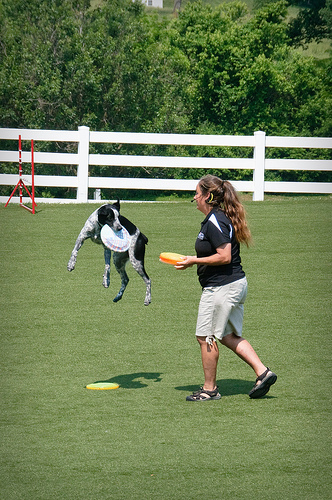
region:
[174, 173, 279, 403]
a woman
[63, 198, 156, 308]
a dog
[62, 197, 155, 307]
the dog is catching a frisbee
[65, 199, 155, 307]
the dog is in the air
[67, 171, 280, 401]
the woman is playing with a dog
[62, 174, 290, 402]
the woman tosses frisbees to the dog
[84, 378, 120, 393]
a yellow frisbee is on the ground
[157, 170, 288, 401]
the woman is holding a frisbee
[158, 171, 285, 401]
the woman is wearing a headset microphone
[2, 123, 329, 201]
a white fence beside the field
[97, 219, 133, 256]
a white frisbee in a dog's mouth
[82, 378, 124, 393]
a yellow frisbee on the ground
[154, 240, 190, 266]
an orange frisbee in a woman's hands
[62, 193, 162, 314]
a dog jumping with a frisbee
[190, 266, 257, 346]
tan shorts on a woman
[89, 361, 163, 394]
the shadow of a dog on the ground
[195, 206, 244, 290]
a black shirt on a woman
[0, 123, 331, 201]
a white wooden fence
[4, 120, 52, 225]
red metal poles near a fence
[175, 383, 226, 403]
a sandal on a woman's foot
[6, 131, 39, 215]
red metal obstacle course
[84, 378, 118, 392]
yellow and green frisbee on ground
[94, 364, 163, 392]
shadow of dog on ground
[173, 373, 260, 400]
shadow of woman on ground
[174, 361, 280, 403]
brown camp sandals on woman's feet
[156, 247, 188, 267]
two frisbees in woman's hands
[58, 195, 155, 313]
dog catching frisbee mid-flight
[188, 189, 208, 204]
face microphone on woman's head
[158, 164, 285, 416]
woman with long, brown hair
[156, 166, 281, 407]
woman performing tricks with dog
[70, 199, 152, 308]
black and white dog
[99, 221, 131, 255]
white and blue frisbee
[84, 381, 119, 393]
yellow frisbee on ground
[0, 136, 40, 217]
red metal barricade fence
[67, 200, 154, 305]
dog catching white frisbee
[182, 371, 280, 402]
black and white sneakers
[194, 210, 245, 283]
black and white polo shirt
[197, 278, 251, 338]
tan khaki cotton shorts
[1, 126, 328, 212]
white wood picket fence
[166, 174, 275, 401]
woman throwing frisbees to dog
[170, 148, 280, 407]
dog trainer with dog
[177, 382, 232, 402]
sandals on dog trainer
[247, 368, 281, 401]
sandal on dog trainer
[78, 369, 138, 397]
yellow frisbee on grass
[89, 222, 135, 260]
frisbee in dog's mouth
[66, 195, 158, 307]
black and grey dog in air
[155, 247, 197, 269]
yellow frisbee in lady's hand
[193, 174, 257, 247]
wavy ponytail of lady's hair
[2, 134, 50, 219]
red training tool on side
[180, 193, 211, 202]
headset on lady's face